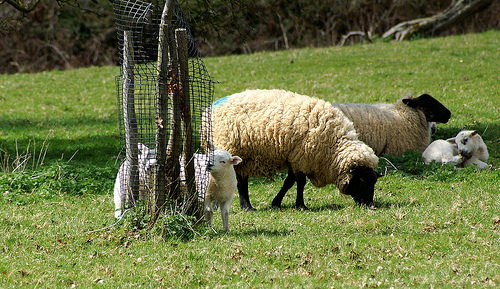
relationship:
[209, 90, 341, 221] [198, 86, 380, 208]
body of sheep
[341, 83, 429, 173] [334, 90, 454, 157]
body of sheep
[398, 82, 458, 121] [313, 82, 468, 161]
head of sheep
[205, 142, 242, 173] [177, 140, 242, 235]
head of sheep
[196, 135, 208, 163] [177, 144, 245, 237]
ear of sheep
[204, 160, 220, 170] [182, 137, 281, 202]
nose of sheep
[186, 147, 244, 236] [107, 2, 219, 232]
lamb by wire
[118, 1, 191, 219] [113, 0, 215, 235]
posts with wire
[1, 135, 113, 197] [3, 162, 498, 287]
weeds in grass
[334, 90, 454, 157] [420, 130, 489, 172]
sheep lies with sheep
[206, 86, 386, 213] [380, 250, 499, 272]
sheep in field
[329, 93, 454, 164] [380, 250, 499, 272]
sheep in field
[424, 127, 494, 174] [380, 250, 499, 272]
sheep in field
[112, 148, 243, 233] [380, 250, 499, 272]
lamb in field